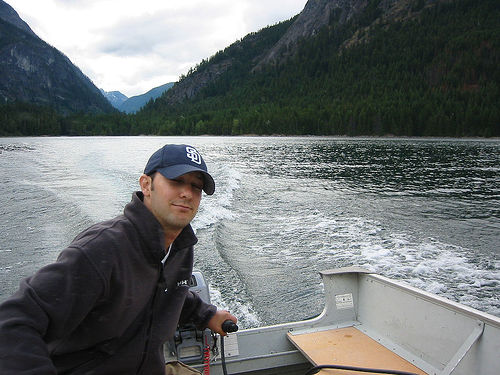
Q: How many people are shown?
A: 1.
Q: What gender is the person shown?
A: Male.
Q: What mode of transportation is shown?
A: Boat.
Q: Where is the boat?
A: Water.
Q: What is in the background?
A: Mountains.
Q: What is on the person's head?
A: Cap.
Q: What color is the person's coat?
A: Dark gray.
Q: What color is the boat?
A: White.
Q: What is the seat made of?
A: Wood.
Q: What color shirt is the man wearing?
A: White.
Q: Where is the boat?
A: In the water.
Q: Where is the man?
A: On a boat.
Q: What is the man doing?
A: Driving a boat.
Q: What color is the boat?
A: White.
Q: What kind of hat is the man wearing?
A: Baseball cap.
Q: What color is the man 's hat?
A: Blue.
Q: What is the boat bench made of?
A: Wood.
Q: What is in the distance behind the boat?
A: Tree covered mountains.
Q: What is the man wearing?
A: Gray jacket and cap.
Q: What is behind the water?
A: Mountains.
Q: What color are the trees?
A: Green.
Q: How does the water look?
A: Choppy.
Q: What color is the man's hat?
A: Blue.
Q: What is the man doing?
A: Driving a boat.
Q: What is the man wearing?
A: A grey sweater.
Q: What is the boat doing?
A: Driving.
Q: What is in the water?
A: Waves.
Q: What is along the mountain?
A: Trees.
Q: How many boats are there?
A: 1.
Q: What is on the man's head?
A: A hat.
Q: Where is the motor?
A: Behind the man's hand.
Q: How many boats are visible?
A: One.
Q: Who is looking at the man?
A: The photographer.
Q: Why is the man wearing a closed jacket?
A: It's cold out.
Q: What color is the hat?
A: Blue.